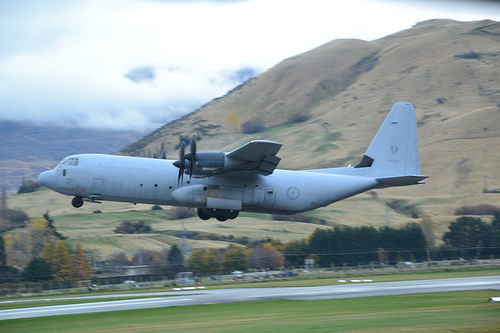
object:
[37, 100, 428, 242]
plane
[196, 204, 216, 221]
wheels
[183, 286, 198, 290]
marks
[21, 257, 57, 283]
tree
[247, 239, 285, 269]
trees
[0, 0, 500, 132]
clouds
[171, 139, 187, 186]
propellers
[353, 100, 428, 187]
tail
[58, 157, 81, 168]
windshield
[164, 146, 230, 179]
engines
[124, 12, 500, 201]
mountain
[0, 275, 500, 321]
runway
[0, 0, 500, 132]
sky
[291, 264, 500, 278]
fence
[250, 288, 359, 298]
line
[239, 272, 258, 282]
cars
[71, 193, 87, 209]
front tire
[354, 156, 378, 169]
black area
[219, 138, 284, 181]
wing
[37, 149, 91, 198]
front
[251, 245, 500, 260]
power lines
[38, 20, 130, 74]
air